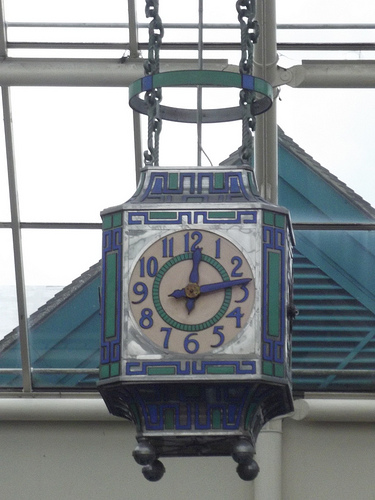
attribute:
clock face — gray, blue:
[122, 211, 262, 382]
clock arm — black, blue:
[169, 278, 252, 301]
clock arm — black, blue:
[186, 245, 203, 316]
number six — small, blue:
[180, 330, 201, 356]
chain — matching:
[236, 0, 262, 166]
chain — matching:
[145, 1, 165, 165]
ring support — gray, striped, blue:
[128, 69, 275, 124]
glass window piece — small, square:
[9, 86, 130, 222]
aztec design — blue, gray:
[99, 167, 298, 482]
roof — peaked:
[1, 125, 374, 389]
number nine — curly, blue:
[129, 282, 150, 307]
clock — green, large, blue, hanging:
[97, 166, 299, 483]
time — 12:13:
[125, 227, 256, 354]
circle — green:
[154, 252, 233, 332]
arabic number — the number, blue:
[183, 232, 205, 255]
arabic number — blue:
[139, 307, 155, 330]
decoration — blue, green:
[140, 171, 255, 204]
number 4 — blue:
[225, 306, 247, 329]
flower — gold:
[183, 282, 200, 300]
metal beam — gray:
[1, 56, 374, 86]